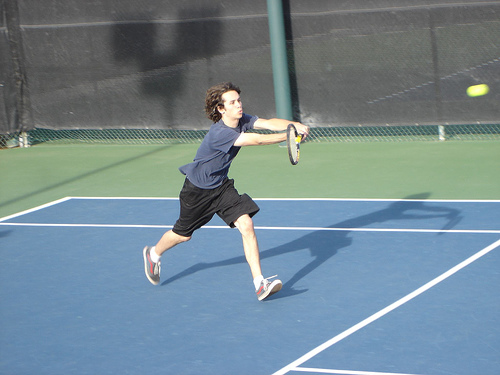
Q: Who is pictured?
A: A tennis player.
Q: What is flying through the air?
A: A tennis ball.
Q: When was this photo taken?
A: During the afternoon.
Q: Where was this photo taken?
A: On a tennis court.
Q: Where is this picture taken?
A: On a tennis court?.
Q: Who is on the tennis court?
A: A man.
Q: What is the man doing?
A: Swinging the tennis racquet.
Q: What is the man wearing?
A: Blue shirt and black shorts.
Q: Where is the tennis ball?
A: In air in front of the man.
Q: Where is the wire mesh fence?
A: At the far end of the court.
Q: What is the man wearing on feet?
A: Blue and red tennis shoes.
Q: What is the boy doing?
A: Playing tennis.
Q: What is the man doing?
A: Playing tennis.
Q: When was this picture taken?
A: Day time.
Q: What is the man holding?
A: A tennis racquet.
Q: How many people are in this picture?
A: One.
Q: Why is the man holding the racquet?
A: To hit the ball.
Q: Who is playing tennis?
A: Then man.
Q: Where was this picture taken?
A: A tennis court.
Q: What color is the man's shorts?
A: Black.